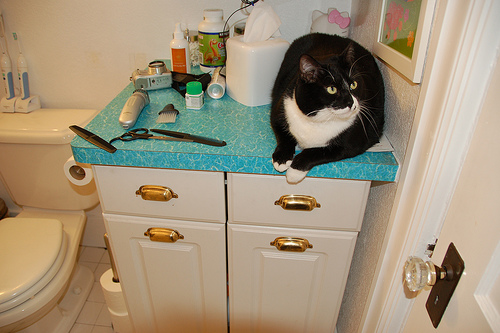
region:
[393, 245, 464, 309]
a crystal door knob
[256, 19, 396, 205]
a black and white cat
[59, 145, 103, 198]
a rol of toilet paper on the holder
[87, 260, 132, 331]
two extra rollas of toilet paper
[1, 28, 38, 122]
two blue and white electric toothbrushes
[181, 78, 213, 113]
a pill bottle with a green lid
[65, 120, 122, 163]
a comb on the corner of the cabinet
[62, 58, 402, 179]
a blue counter top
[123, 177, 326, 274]
gold drawer pulls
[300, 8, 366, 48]
the top of hello kitty's head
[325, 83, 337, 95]
a cat's right eye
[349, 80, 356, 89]
a cat's left eye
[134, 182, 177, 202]
a golden handle on a cabinet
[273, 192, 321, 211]
a golden handle on a cabinet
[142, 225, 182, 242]
a golden handle on a cabinet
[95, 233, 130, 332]
rolls of toilet paper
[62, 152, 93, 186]
a roll of toilet paper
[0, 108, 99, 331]
a white porcelain toilet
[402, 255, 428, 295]
a faux crystal door knob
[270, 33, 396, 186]
a cat sitting on a counter top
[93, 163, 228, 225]
a drawer under the counter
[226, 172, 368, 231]
a drawer under the counter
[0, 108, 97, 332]
a white toilet tank and bowl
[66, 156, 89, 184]
a white roll of toilet paper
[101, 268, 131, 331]
two rolls of toilet paper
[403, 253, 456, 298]
a clear door knob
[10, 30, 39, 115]
a white electric toothbrush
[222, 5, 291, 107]
a white box of tissues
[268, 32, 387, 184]
A black and white cat laying on a counter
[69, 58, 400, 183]
A turquoise colored laminated countertop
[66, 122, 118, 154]
A black hair comb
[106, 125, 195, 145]
Black plastic handle scissors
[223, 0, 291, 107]
White facial tissue dispenser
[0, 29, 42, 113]
Two electric toothbrushes sitting upright in stands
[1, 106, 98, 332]
An off-white ceramic toilet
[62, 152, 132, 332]
Three rolls of toilet paper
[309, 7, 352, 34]
Hello Kitty with a pink bow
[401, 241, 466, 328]
Metal door handle plate with crystal knob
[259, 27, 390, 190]
the cat is sitting on the counter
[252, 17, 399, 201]
the cat is black and white in color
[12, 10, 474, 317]
this room is the bathroom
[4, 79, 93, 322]
this is the toilet in the bathroom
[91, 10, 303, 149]
there are many items on the counter top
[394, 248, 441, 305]
this is the bathroom doors, door knob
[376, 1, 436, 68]
a picture hanging on the wall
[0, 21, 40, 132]
toothbrushes are on the tank of the toilet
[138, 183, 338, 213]
the handles for the drawers are gold